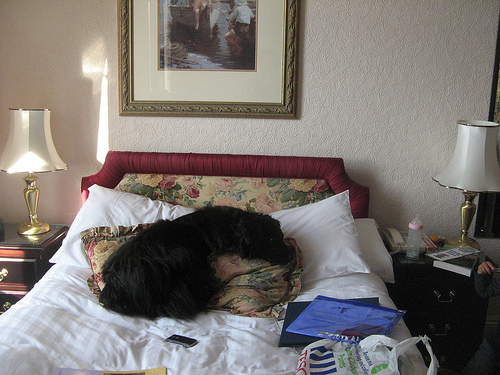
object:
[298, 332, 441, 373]
plastic bag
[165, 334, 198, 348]
cellphone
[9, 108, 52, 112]
gold outline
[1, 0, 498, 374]
bedroom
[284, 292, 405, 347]
shirt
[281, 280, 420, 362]
shirt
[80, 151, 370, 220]
floral headboard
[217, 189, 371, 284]
pillow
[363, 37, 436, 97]
table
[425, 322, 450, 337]
handle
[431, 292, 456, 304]
handle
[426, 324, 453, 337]
gold handle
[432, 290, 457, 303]
gold handle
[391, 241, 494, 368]
small dresser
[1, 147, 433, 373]
bed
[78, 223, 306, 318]
bus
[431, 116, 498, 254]
lamps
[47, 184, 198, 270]
pillow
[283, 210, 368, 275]
pillow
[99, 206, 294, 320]
dog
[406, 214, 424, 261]
bottle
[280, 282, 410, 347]
shirt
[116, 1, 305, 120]
picture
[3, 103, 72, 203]
sunlight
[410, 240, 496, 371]
chair